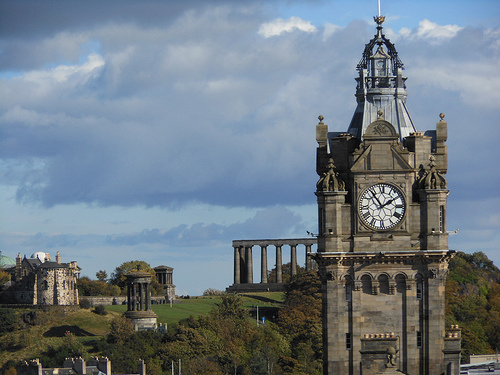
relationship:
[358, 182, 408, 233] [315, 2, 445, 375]
clock on tower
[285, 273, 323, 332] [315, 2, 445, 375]
tree behind tower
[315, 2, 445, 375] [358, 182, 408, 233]
tower has clock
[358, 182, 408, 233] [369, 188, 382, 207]
clock has hand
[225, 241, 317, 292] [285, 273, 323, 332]
building behind tree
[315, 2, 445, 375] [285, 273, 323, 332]
tower in front of tree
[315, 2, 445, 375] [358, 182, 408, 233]
tower above clock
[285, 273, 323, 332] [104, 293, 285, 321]
tree near field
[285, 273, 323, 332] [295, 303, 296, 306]
tree has leaf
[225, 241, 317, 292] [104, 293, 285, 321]
building on top of field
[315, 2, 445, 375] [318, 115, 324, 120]
tower has sphere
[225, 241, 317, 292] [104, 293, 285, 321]
building in field